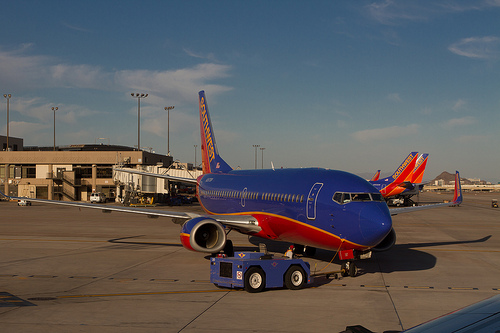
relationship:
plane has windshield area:
[4, 88, 461, 276] [331, 190, 385, 202]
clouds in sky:
[3, 42, 239, 109] [0, 1, 497, 195]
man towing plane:
[284, 245, 296, 259] [0, 90, 464, 277]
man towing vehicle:
[284, 245, 296, 259] [210, 252, 311, 293]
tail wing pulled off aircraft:
[195, 90, 226, 176] [1, 87, 464, 272]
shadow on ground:
[106, 234, 493, 279] [320, 217, 482, 319]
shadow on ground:
[106, 234, 493, 279] [421, 237, 469, 292]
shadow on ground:
[106, 234, 493, 279] [2, 190, 497, 328]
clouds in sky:
[0, 41, 235, 110] [268, 42, 405, 103]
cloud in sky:
[0, 92, 99, 140] [151, 7, 273, 39]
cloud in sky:
[447, 36, 500, 60] [151, 7, 273, 39]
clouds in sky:
[0, 41, 235, 110] [151, 7, 273, 39]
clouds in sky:
[0, 41, 235, 110] [282, 77, 334, 169]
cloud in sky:
[447, 36, 500, 60] [282, 77, 334, 169]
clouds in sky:
[0, 41, 235, 110] [0, 1, 497, 195]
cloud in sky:
[0, 92, 99, 140] [0, 1, 497, 195]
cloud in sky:
[444, 22, 499, 63] [0, 1, 497, 195]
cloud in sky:
[447, 36, 500, 60] [0, 1, 499, 181]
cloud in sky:
[348, 121, 424, 145] [0, 1, 499, 181]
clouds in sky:
[0, 41, 235, 110] [0, 1, 499, 181]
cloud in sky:
[0, 92, 99, 140] [0, 1, 499, 181]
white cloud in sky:
[308, 146, 373, 168] [0, 1, 499, 181]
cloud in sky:
[308, 21, 488, 161] [263, 25, 422, 107]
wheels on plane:
[338, 259, 360, 276] [4, 88, 461, 276]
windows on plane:
[197, 187, 309, 209] [1, 82, 408, 281]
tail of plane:
[112, 87, 234, 223] [4, 88, 461, 276]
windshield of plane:
[336, 190, 385, 206] [16, 90, 407, 314]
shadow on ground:
[106, 234, 493, 279] [2, 175, 499, 330]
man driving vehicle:
[276, 241, 303, 264] [211, 207, 351, 308]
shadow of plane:
[106, 232, 491, 274] [4, 88, 461, 276]